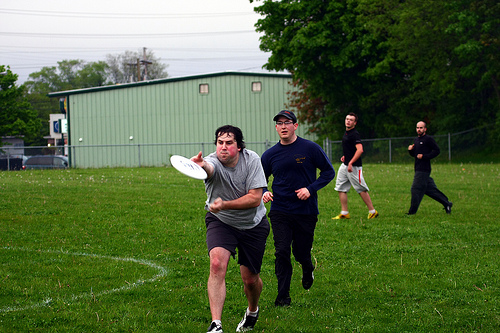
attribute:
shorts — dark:
[201, 204, 272, 276]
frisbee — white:
[161, 151, 228, 193]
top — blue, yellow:
[265, 142, 331, 204]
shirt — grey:
[199, 154, 274, 232]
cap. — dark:
[271, 103, 305, 125]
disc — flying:
[163, 154, 211, 184]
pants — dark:
[192, 203, 252, 283]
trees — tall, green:
[1, 50, 175, 152]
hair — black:
[208, 121, 247, 154]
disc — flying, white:
[164, 151, 216, 181]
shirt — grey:
[202, 148, 272, 228]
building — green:
[49, 67, 330, 169]